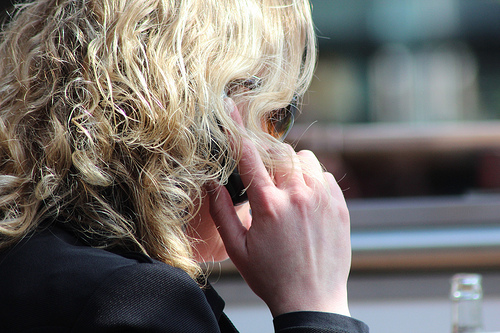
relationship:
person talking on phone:
[1, 0, 374, 333] [175, 82, 269, 192]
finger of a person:
[222, 92, 267, 193] [1, 0, 374, 333]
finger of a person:
[206, 178, 246, 254] [1, 0, 374, 333]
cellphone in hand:
[200, 110, 253, 207] [192, 98, 355, 299]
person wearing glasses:
[1, 0, 374, 333] [249, 84, 299, 144]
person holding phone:
[1, 0, 363, 330] [206, 69, 256, 207]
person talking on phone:
[1, 0, 374, 333] [198, 77, 254, 199]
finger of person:
[206, 178, 246, 254] [1, 0, 374, 333]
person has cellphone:
[1, 0, 374, 333] [200, 110, 253, 207]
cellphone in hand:
[200, 110, 253, 207] [200, 93, 358, 318]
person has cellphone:
[1, 0, 374, 333] [200, 110, 250, 202]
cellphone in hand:
[200, 110, 250, 202] [205, 95, 349, 301]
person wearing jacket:
[1, 0, 374, 333] [0, 180, 374, 328]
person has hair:
[1, 0, 374, 333] [2, 0, 319, 283]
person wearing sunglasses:
[1, 0, 374, 333] [263, 107, 295, 137]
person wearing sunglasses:
[1, 0, 374, 333] [270, 106, 295, 135]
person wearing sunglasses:
[1, 0, 374, 333] [263, 101, 294, 137]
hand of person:
[205, 95, 349, 301] [1, 0, 374, 333]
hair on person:
[2, 0, 319, 283] [1, 0, 374, 333]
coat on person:
[0, 185, 364, 330] [1, 0, 374, 333]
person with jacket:
[1, 0, 374, 333] [0, 180, 374, 328]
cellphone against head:
[200, 110, 253, 207] [4, 3, 303, 267]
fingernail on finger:
[221, 96, 237, 111] [213, 96, 272, 201]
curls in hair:
[66, 71, 208, 231] [2, 0, 319, 283]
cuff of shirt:
[272, 309, 372, 331] [1, 202, 241, 332]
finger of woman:
[206, 178, 246, 254] [193, 92, 359, 314]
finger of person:
[219, 95, 280, 217] [1, 0, 374, 333]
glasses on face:
[249, 84, 299, 144] [212, 76, 297, 144]